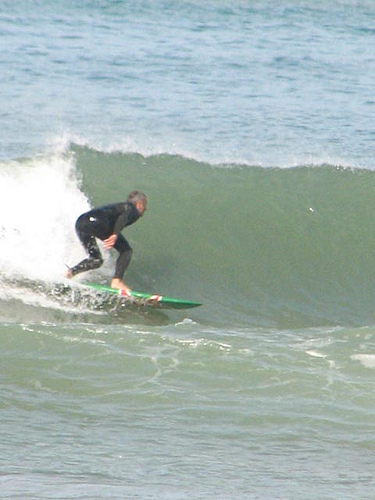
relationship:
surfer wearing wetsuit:
[64, 190, 154, 295] [72, 198, 139, 277]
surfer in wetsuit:
[64, 190, 154, 295] [72, 198, 139, 277]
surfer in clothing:
[64, 190, 154, 295] [68, 201, 141, 281]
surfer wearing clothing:
[64, 190, 154, 295] [72, 200, 140, 281]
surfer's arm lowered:
[64, 190, 154, 295] [101, 205, 136, 251]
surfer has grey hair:
[64, 190, 154, 295] [127, 190, 148, 206]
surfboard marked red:
[8, 268, 205, 313] [149, 295, 160, 306]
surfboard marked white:
[8, 268, 205, 313] [145, 294, 165, 304]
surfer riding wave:
[64, 190, 154, 295] [57, 134, 374, 326]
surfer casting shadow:
[64, 190, 154, 295] [1, 303, 172, 335]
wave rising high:
[57, 134, 374, 326] [40, 130, 373, 189]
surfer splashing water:
[64, 190, 154, 295] [0, 138, 64, 314]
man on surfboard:
[64, 190, 154, 295] [8, 268, 205, 313]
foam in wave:
[1, 138, 96, 267] [57, 134, 374, 326]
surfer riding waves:
[64, 190, 154, 295] [57, 134, 374, 326]